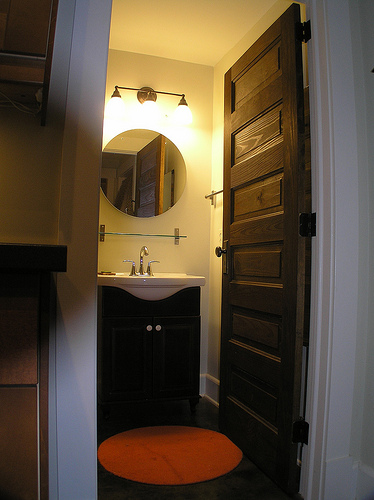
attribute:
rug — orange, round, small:
[99, 424, 246, 488]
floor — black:
[96, 397, 294, 498]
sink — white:
[115, 272, 184, 279]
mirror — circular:
[102, 130, 184, 216]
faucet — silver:
[139, 246, 147, 275]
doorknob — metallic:
[215, 248, 226, 258]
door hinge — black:
[300, 209, 318, 235]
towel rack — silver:
[203, 190, 223, 204]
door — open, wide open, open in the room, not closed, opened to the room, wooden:
[220, 4, 302, 487]